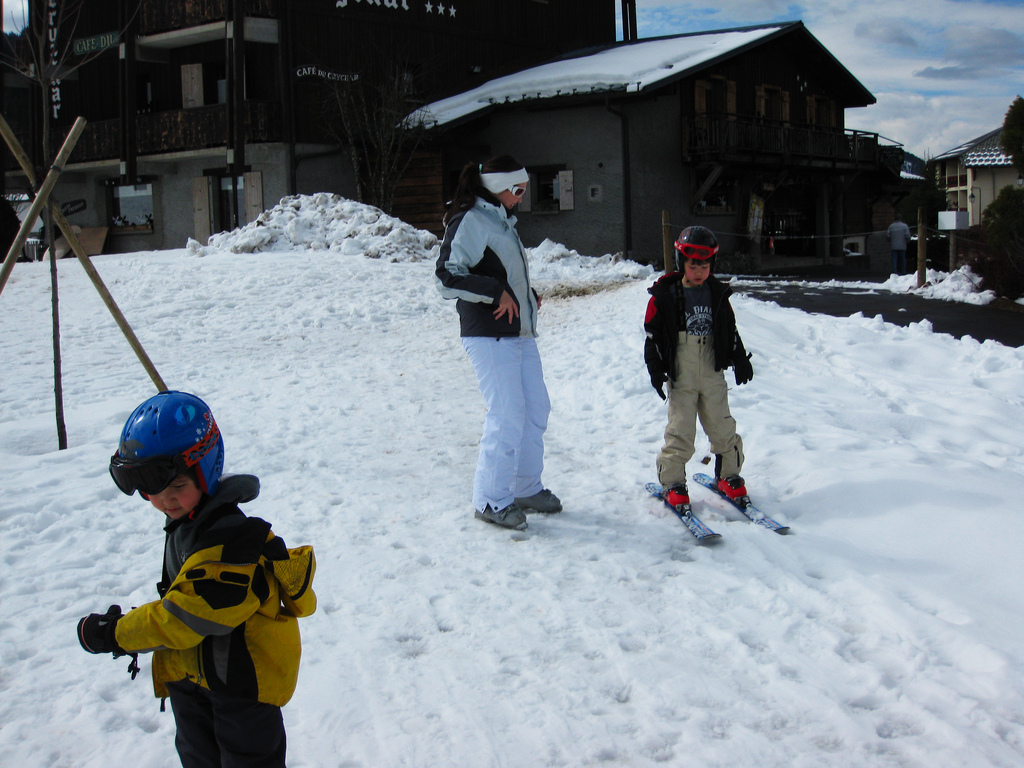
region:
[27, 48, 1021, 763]
people standing on the snow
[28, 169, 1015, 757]
tracks on the snow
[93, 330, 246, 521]
a dark blue helmet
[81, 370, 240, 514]
goggles on the helmet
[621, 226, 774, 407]
boy wearing a black jacket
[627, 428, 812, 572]
a pair of skis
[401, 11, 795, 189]
snow on a roof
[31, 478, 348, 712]
boy wearing a yellow jacket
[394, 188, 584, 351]
a white and black jacket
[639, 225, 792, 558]
a child wearing a pair of skis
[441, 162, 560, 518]
a woman that is wearing white ski pants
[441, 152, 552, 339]
a woman wearing a black and white coat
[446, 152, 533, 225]
a woman wearing a white head band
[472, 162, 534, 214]
a woman that is wearing a pair of sunglasses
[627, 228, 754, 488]
a boy that is wearing tan ski pants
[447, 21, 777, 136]
snow on the roof of a building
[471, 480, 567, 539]
a person wearing grey ski boots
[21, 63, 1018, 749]
picture taken outdoors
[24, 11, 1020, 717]
picture taken during the day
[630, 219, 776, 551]
a boy is wearing skies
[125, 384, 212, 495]
the boy wears a blue helmet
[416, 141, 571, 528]
a woman stands next to a boy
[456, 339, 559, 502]
the woman wears white snow pants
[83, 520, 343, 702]
the boy wears a yellow and black ski coat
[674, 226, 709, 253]
the boy has a black helmet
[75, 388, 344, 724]
A little boy wearing a yellow jacket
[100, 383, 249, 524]
A little boy wearing a ski helmet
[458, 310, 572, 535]
A pair of white ski pants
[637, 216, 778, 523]
a boy wearing beige ski pants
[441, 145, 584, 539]
a woman wearing white ski pants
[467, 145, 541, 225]
A woman wearing sunglasses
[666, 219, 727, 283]
a black helmet with red ski goggles on it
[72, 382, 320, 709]
a boy wearing ski gloves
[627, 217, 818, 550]
boy in black coat on skies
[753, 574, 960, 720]
footprints in the snow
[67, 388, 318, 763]
boy wearing blue helmet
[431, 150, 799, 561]
woman in white watching boy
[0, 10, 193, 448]
bamboo pole securing tree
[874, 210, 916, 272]
man in grey shirt by building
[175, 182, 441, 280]
dirty snow piled up by building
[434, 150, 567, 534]
woman in white and black jacket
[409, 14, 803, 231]
snow on top of roof of building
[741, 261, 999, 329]
snow cleared off of driveway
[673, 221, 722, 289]
Helmet on a boy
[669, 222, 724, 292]
Black helmet on a boy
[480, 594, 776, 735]
Large patch of snow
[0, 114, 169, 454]
tripod made from bamboo poles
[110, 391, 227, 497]
childs blue ski helmet with goggles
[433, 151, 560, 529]
brunette woman in snow clothing watching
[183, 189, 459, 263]
piled up mound of dirt and snow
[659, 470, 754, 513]
red ski boots being used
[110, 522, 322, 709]
yellow snow jacket being worn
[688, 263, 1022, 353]
street cleared of snow but with snow on edge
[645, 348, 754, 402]
dark ski gloves being worn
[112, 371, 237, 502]
boy wearing safety helmet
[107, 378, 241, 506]
boys helmet is blue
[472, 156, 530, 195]
woman wearing head wrap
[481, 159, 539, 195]
womans wrap is white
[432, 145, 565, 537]
a woman wearing white pants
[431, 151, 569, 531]
a woman wearing a black and grey coat